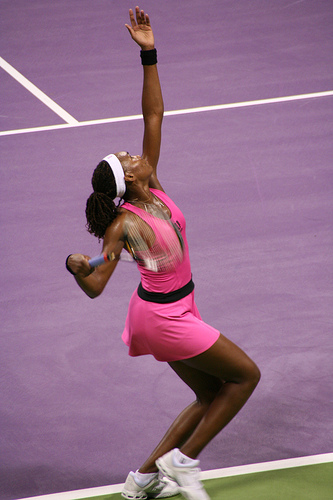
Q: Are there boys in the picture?
A: No, there are no boys.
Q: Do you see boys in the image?
A: No, there are no boys.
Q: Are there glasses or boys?
A: No, there are no boys or glasses.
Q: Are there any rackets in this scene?
A: Yes, there is a racket.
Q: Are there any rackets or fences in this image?
A: Yes, there is a racket.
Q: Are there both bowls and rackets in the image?
A: No, there is a racket but no bowls.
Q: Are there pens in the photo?
A: No, there are no pens.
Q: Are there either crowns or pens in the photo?
A: No, there are no pens or crowns.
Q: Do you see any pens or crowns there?
A: No, there are no pens or crowns.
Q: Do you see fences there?
A: No, there are no fences.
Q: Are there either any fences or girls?
A: No, there are no fences or girls.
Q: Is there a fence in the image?
A: No, there are no fences.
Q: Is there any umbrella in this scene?
A: No, there are no umbrellas.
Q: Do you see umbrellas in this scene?
A: No, there are no umbrellas.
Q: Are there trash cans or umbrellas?
A: No, there are no umbrellas or trash cans.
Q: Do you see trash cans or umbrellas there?
A: No, there are no umbrellas or trash cans.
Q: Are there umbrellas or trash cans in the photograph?
A: No, there are no umbrellas or trash cans.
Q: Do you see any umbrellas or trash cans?
A: No, there are no umbrellas or trash cans.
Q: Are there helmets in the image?
A: No, there are no helmets.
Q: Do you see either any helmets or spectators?
A: No, there are no helmets or spectators.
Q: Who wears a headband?
A: The player wears a headband.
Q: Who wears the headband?
A: The player wears a headband.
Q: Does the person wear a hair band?
A: Yes, the player wears a hair band.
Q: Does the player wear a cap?
A: No, the player wears a hair band.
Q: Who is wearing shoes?
A: The player is wearing shoes.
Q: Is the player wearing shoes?
A: Yes, the player is wearing shoes.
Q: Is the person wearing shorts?
A: No, the player is wearing shoes.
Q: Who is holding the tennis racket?
A: The player is holding the tennis racket.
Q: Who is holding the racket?
A: The player is holding the tennis racket.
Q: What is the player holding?
A: The player is holding the racket.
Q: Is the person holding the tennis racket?
A: Yes, the player is holding the tennis racket.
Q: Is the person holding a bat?
A: No, the player is holding the tennis racket.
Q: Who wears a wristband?
A: The player wears a wristband.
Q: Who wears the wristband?
A: The player wears a wristband.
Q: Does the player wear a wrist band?
A: Yes, the player wears a wrist band.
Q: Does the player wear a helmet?
A: No, the player wears a wrist band.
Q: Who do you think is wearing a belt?
A: The player is wearing a belt.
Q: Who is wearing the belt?
A: The player is wearing a belt.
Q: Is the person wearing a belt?
A: Yes, the player is wearing a belt.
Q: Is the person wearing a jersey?
A: No, the player is wearing a belt.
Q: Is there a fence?
A: No, there are no fences.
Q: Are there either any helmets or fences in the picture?
A: No, there are no fences or helmets.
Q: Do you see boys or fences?
A: No, there are no fences or boys.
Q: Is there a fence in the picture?
A: No, there are no fences.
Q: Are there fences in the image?
A: No, there are no fences.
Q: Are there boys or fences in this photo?
A: No, there are no fences or boys.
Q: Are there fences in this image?
A: No, there are no fences.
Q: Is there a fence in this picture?
A: No, there are no fences.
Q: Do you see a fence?
A: No, there are no fences.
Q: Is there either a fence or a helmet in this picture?
A: No, there are no fences or helmets.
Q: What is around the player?
A: The belt is around the player.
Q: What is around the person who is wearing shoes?
A: The belt is around the player.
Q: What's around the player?
A: The belt is around the player.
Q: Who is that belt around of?
A: The belt is around the player.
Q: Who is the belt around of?
A: The belt is around the player.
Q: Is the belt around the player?
A: Yes, the belt is around the player.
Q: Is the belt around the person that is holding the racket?
A: Yes, the belt is around the player.